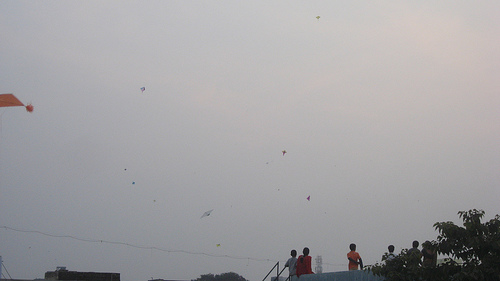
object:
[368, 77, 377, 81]
white clouds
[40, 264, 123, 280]
top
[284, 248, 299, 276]
person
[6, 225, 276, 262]
power line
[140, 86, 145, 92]
kite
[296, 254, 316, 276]
dress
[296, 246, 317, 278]
woman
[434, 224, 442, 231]
leaves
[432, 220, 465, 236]
branch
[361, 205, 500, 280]
tree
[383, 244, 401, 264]
people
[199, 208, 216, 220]
kite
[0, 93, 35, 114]
kite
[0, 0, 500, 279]
sky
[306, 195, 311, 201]
kite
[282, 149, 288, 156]
kite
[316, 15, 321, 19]
kite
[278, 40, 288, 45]
clouds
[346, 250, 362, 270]
shirt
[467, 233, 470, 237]
leaves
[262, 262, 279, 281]
rails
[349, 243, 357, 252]
head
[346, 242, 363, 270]
boy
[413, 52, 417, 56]
clouds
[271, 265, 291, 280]
stairs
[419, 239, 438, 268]
people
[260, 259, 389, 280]
place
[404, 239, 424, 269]
people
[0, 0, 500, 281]
cloud